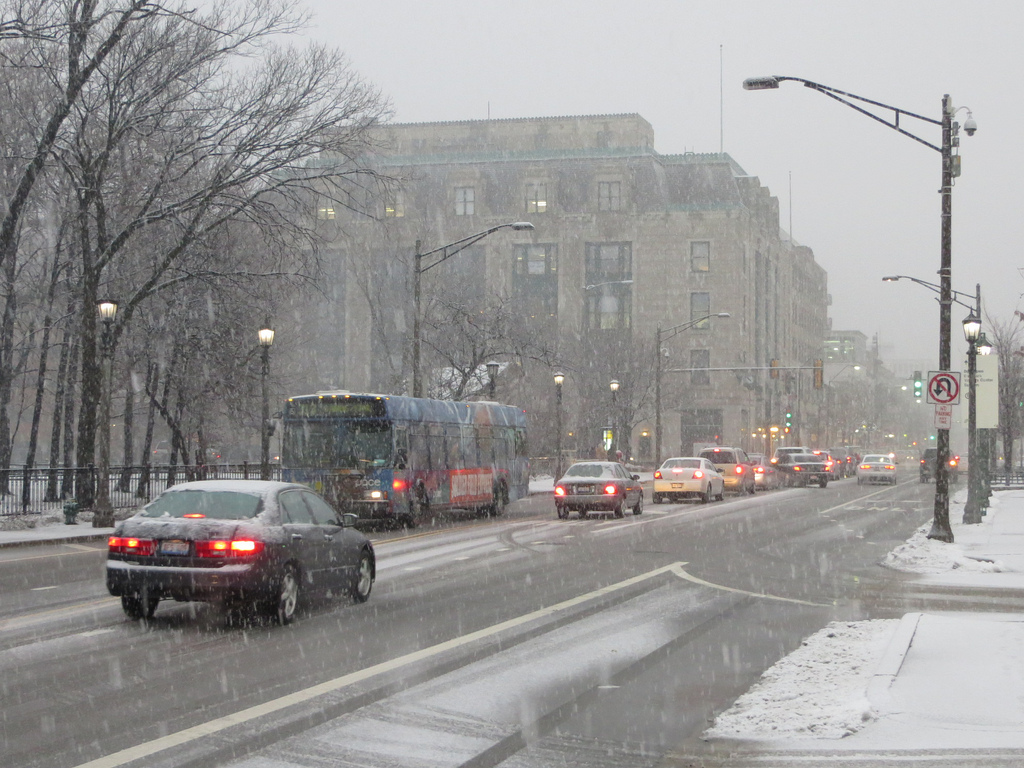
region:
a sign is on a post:
[929, 354, 967, 469]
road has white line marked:
[341, 529, 699, 717]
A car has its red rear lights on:
[105, 451, 383, 649]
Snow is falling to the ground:
[150, 156, 867, 704]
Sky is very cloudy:
[546, 26, 703, 90]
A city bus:
[247, 349, 592, 573]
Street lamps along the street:
[70, 217, 699, 552]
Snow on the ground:
[788, 628, 1014, 750]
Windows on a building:
[382, 149, 655, 248]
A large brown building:
[244, 59, 813, 529]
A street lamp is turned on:
[210, 273, 321, 409]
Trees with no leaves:
[74, 16, 399, 320]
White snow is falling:
[41, 90, 914, 706]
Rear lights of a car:
[74, 497, 288, 588]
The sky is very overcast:
[431, 10, 688, 84]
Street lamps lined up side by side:
[56, 259, 654, 512]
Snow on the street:
[438, 583, 724, 729]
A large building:
[234, 76, 864, 499]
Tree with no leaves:
[54, 23, 348, 496]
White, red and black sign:
[905, 351, 975, 419]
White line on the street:
[437, 558, 725, 610]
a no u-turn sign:
[917, 360, 972, 409]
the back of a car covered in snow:
[88, 474, 405, 643]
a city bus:
[259, 388, 544, 531]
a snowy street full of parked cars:
[104, 219, 943, 725]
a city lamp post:
[644, 300, 744, 484]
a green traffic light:
[900, 355, 932, 425]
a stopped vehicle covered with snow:
[547, 443, 643, 535]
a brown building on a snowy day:
[231, 137, 865, 520]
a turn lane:
[799, 420, 997, 551]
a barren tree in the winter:
[25, 137, 399, 564]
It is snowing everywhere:
[105, 236, 903, 679]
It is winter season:
[55, 49, 1005, 739]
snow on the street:
[728, 574, 991, 749]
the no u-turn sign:
[912, 354, 979, 413]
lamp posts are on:
[76, 275, 317, 362]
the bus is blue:
[289, 383, 545, 516]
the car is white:
[650, 449, 726, 508]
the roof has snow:
[128, 469, 360, 515]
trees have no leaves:
[11, 16, 258, 456]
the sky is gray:
[384, 7, 973, 138]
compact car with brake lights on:
[98, 473, 390, 635]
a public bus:
[269, 385, 545, 528]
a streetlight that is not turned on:
[731, 66, 972, 547]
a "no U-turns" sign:
[917, 366, 966, 406]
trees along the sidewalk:
[7, 0, 355, 531]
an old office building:
[164, 106, 844, 493]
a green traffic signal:
[906, 365, 930, 407]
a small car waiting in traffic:
[549, 458, 654, 520]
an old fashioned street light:
[82, 290, 122, 524]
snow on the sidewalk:
[850, 621, 1019, 729]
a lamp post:
[745, 67, 960, 552]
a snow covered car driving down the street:
[80, 472, 407, 641]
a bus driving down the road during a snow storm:
[288, 391, 554, 535]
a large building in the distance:
[252, 121, 829, 431]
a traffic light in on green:
[913, 366, 926, 405]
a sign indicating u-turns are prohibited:
[920, 366, 978, 412]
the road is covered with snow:
[380, 563, 911, 750]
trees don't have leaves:
[16, 1, 311, 470]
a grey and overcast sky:
[364, 3, 688, 101]